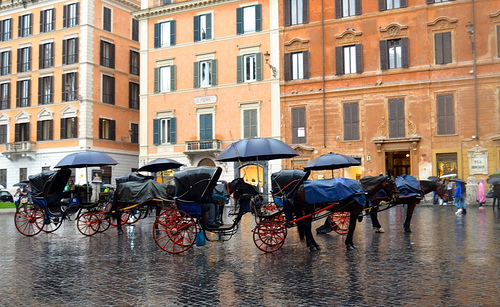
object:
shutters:
[237, 52, 263, 84]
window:
[243, 53, 257, 83]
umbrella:
[215, 138, 301, 185]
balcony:
[1, 141, 38, 154]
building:
[0, 0, 500, 205]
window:
[200, 59, 212, 87]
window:
[160, 65, 170, 92]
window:
[236, 5, 261, 35]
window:
[342, 46, 356, 75]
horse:
[290, 174, 399, 251]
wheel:
[252, 222, 287, 253]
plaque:
[468, 144, 488, 175]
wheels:
[153, 209, 198, 253]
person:
[452, 180, 465, 215]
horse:
[110, 179, 176, 235]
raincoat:
[117, 179, 167, 203]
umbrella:
[138, 157, 184, 182]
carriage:
[152, 166, 340, 253]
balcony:
[182, 138, 222, 155]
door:
[200, 113, 212, 149]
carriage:
[14, 168, 162, 236]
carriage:
[103, 171, 184, 226]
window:
[437, 94, 453, 136]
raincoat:
[476, 178, 486, 204]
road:
[0, 205, 499, 307]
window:
[153, 19, 174, 48]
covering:
[304, 177, 372, 207]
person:
[476, 178, 486, 210]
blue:
[453, 181, 462, 198]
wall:
[278, 29, 497, 195]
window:
[15, 46, 30, 74]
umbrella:
[54, 152, 118, 203]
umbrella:
[303, 152, 358, 179]